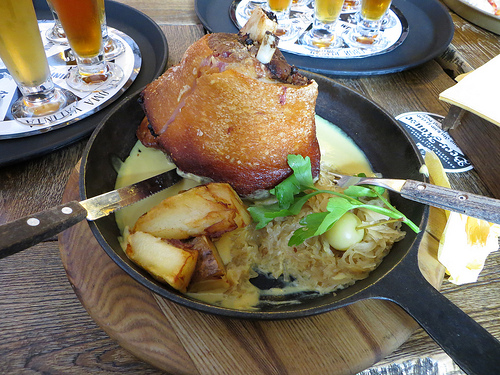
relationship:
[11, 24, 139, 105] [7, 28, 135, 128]
beer on tray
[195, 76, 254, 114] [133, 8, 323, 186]
skin on meat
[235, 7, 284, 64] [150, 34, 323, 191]
bone in meat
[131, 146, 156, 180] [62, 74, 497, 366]
sauce in skillet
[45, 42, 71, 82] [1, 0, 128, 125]
paper in tray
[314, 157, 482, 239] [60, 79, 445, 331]
fork on pan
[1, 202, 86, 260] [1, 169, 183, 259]
handle on knife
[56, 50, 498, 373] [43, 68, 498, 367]
pan on board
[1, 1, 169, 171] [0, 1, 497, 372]
tray on table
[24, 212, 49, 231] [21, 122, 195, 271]
circle on knife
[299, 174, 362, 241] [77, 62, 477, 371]
parsley lying in pan